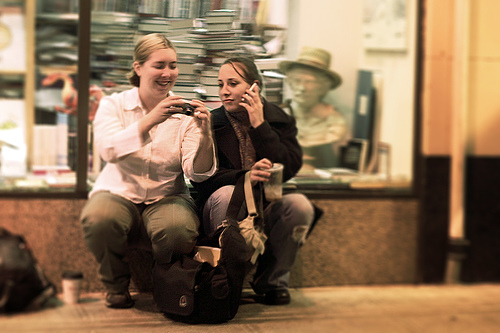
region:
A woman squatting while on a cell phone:
[203, 55, 313, 317]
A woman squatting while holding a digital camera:
[81, 30, 218, 310]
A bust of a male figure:
[274, 66, 348, 149]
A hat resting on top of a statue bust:
[265, 37, 350, 86]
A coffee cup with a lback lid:
[63, 266, 85, 301]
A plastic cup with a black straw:
[259, 162, 288, 201]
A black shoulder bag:
[162, 221, 251, 330]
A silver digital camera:
[167, 94, 203, 115]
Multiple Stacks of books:
[2, 1, 288, 133]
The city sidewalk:
[0, 290, 499, 331]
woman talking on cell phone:
[195, 55, 316, 311]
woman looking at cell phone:
[80, 28, 214, 290]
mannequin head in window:
[266, 36, 342, 166]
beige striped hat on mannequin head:
[274, 38, 349, 90]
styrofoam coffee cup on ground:
[60, 263, 89, 307]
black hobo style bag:
[149, 213, 256, 331]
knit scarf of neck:
[220, 107, 261, 187]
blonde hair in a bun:
[122, 25, 188, 102]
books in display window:
[167, 8, 282, 119]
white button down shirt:
[87, 88, 220, 208]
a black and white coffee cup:
[62, 270, 84, 303]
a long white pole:
[446, 0, 476, 287]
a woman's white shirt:
[85, 86, 220, 220]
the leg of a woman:
[138, 191, 200, 302]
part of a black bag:
[0, 228, 57, 318]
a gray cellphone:
[242, 82, 256, 100]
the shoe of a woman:
[249, 270, 294, 305]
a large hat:
[272, 48, 349, 89]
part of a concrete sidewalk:
[299, 283, 499, 331]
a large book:
[138, 21, 188, 34]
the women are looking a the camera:
[78, 31, 407, 327]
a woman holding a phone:
[211, 53, 276, 157]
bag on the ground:
[157, 193, 264, 330]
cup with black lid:
[42, 258, 103, 315]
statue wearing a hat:
[258, 30, 353, 146]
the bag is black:
[178, 210, 250, 325]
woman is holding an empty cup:
[223, 110, 285, 237]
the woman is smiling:
[138, 28, 193, 131]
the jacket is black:
[212, 104, 285, 221]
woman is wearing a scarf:
[206, 93, 307, 251]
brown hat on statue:
[264, 37, 351, 87]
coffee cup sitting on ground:
[60, 255, 91, 311]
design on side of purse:
[175, 280, 195, 308]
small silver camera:
[169, 88, 210, 123]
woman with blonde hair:
[106, 23, 201, 97]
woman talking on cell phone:
[216, 33, 287, 121]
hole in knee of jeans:
[286, 223, 312, 250]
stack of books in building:
[172, 8, 268, 57]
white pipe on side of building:
[433, 0, 478, 237]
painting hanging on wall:
[358, 0, 415, 51]